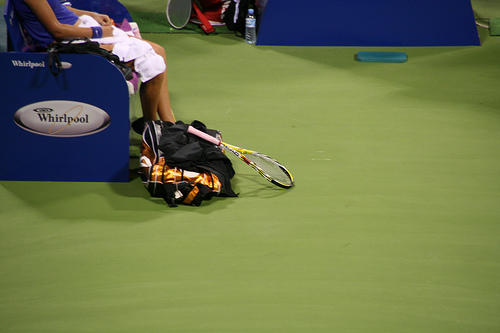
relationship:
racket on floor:
[185, 125, 295, 190] [296, 102, 485, 289]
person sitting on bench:
[10, 0, 177, 136] [1, 1, 131, 181]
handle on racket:
[187, 125, 221, 146] [185, 125, 295, 190]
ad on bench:
[10, 100, 111, 138] [1, 1, 131, 181]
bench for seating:
[0, 0, 135, 183] [15, 34, 117, 187]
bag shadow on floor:
[137, 120, 226, 208] [56, 32, 476, 305]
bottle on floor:
[240, 6, 258, 49] [6, 50, 492, 319]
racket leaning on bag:
[198, 130, 280, 183] [156, 124, 243, 208]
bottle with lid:
[244, 8, 256, 45] [235, 9, 256, 17]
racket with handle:
[185, 125, 295, 190] [186, 117, 233, 151]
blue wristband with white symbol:
[91, 23, 104, 41] [94, 27, 98, 34]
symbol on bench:
[11, 96, 111, 138] [1, 1, 131, 181]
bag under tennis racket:
[159, 119, 217, 168] [185, 124, 293, 188]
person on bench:
[10, 0, 177, 136] [0, 45, 134, 190]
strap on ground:
[192, 10, 220, 41] [201, 37, 357, 155]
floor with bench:
[1, 1, 497, 331] [1, 1, 131, 181]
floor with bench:
[1, 1, 497, 331] [253, 0, 481, 47]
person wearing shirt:
[10, 0, 177, 136] [7, 0, 84, 43]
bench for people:
[6, 44, 131, 195] [80, 23, 310, 268]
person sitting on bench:
[76, 27, 229, 204] [19, 83, 126, 176]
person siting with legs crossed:
[10, 0, 177, 136] [121, 22, 190, 174]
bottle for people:
[244, 8, 256, 45] [91, 22, 283, 242]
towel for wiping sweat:
[76, 10, 167, 82] [46, 15, 74, 37]